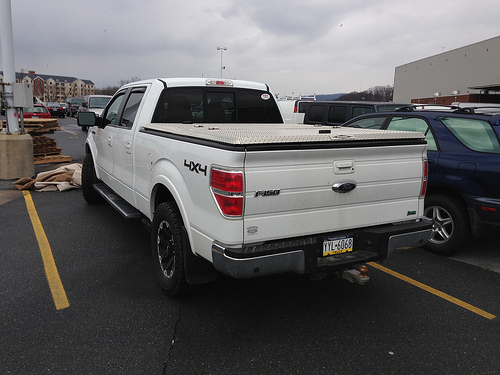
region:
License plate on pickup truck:
[317, 234, 362, 258]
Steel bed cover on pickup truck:
[142, 116, 437, 146]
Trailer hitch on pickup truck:
[347, 260, 379, 293]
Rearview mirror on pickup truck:
[77, 105, 105, 130]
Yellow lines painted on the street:
[15, 198, 72, 317]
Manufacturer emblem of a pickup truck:
[329, 173, 365, 195]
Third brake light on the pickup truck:
[204, 77, 234, 91]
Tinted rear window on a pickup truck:
[147, 81, 288, 128]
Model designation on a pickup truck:
[255, 187, 280, 197]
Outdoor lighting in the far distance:
[212, 43, 234, 77]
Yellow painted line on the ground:
[15, 182, 71, 312]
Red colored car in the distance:
[15, 102, 55, 117]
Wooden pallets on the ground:
[1, 115, 68, 160]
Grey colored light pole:
[0, 0, 30, 130]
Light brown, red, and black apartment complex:
[0, 67, 95, 97]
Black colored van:
[300, 100, 410, 125]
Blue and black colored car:
[336, 107, 496, 247]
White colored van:
[276, 97, 315, 123]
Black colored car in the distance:
[44, 98, 64, 119]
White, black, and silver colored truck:
[75, 78, 430, 290]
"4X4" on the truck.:
[175, 157, 214, 179]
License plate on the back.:
[317, 234, 359, 251]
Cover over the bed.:
[158, 115, 416, 169]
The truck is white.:
[80, 83, 405, 294]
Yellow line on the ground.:
[25, 194, 72, 316]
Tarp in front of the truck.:
[9, 157, 85, 193]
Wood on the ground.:
[31, 130, 69, 164]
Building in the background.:
[18, 68, 100, 105]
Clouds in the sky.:
[47, 10, 215, 62]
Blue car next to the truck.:
[348, 115, 498, 227]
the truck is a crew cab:
[86, 70, 439, 295]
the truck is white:
[102, 75, 435, 288]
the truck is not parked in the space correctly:
[106, 58, 443, 327]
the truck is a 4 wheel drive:
[98, 75, 499, 320]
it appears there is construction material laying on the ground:
[16, 104, 81, 214]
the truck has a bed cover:
[169, 119, 423, 160]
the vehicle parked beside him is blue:
[342, 69, 498, 221]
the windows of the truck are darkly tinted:
[140, 85, 318, 132]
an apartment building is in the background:
[10, 65, 100, 118]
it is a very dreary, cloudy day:
[91, 12, 303, 69]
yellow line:
[10, 228, 81, 329]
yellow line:
[41, 247, 129, 359]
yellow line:
[51, 247, 91, 310]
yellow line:
[5, 211, 110, 349]